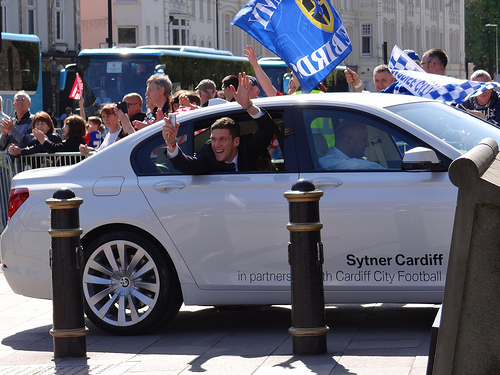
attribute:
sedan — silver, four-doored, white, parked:
[1, 93, 500, 335]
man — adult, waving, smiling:
[162, 71, 289, 176]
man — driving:
[318, 119, 389, 171]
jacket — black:
[166, 113, 281, 171]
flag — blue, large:
[229, 0, 354, 96]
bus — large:
[73, 44, 350, 118]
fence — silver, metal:
[3, 153, 95, 236]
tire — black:
[78, 227, 184, 336]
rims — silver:
[81, 241, 160, 327]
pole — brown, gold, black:
[46, 187, 91, 365]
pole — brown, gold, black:
[283, 179, 331, 356]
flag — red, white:
[69, 73, 84, 102]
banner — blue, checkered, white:
[389, 45, 500, 109]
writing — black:
[236, 252, 446, 284]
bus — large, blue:
[0, 32, 44, 120]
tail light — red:
[7, 187, 29, 220]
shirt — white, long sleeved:
[320, 146, 397, 173]